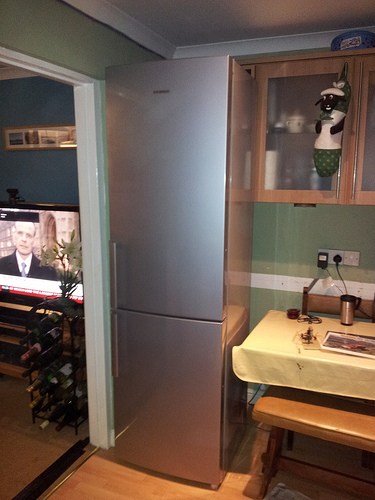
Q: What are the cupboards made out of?
A: Wood and glass.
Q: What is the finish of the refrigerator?
A: Stainless steel.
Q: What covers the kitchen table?
A: A yellow tablecloth.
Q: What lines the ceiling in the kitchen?
A: Molding.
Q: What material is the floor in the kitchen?
A: Wood.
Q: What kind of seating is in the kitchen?
A: Bench seating.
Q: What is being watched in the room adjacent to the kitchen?
A: A television.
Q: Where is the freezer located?
A: Below the refrigerator.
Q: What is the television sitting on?
A: A wood stand.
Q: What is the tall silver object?
A: Refrigerator.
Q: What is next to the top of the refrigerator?
A: Built in cabinet with glass doors.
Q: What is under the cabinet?
A: Table and chair.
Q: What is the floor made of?
A: Wood.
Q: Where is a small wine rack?
A: To the left of the refrigerator.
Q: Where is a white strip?
A: On the kitchen wall.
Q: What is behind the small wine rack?
A: Tv.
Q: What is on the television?
A: A man in a suit.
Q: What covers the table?
A: Tablecloth.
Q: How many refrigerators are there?
A: One.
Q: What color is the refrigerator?
A: Silver.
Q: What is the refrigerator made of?
A: Metal.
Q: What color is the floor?
A: Brown.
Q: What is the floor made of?
A: Wood.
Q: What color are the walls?
A: Green and blue.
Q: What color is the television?
A: Black.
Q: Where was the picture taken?
A: In a kitchen.